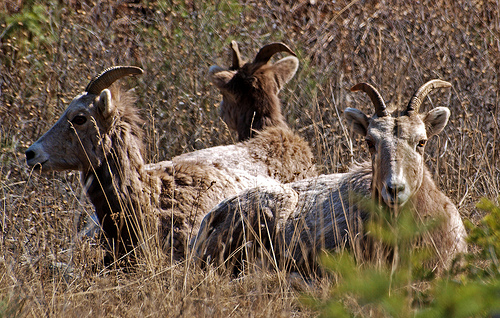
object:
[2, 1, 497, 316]
brown grass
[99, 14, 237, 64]
tree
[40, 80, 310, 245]
ram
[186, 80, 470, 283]
ram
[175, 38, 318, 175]
ram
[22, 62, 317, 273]
ram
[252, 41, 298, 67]
horn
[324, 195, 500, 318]
branch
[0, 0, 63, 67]
tree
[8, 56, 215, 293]
ram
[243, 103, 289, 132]
neck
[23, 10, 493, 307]
field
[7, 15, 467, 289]
grass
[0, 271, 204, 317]
vegetation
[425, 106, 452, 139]
ear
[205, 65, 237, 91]
left ear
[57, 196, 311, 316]
weeds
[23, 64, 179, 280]
animals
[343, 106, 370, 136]
ear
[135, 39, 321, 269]
animal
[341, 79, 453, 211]
head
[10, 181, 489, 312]
ground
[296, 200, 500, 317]
tree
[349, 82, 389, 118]
horn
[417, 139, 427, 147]
eye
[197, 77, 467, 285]
animal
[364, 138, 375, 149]
eye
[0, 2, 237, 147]
bushes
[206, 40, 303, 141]
head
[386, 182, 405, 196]
nose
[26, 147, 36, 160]
nose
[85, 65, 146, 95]
horn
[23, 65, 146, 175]
head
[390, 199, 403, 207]
mouth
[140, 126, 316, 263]
body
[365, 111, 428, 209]
face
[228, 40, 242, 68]
horn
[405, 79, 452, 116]
horn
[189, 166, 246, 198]
fur